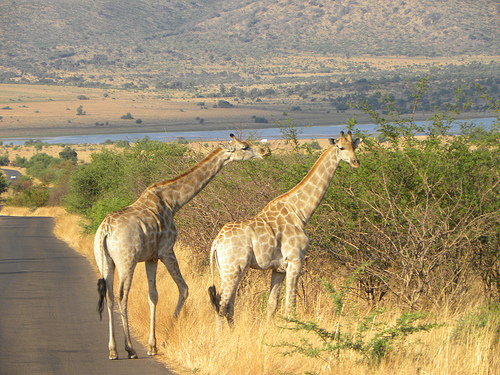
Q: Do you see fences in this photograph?
A: No, there are no fences.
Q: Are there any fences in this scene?
A: No, there are no fences.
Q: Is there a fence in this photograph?
A: No, there are no fences.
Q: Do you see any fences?
A: No, there are no fences.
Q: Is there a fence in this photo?
A: No, there are no fences.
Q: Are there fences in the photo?
A: No, there are no fences.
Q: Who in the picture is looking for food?
A: The animal is looking for food.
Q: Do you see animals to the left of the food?
A: Yes, there is an animal to the left of the food.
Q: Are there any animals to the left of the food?
A: Yes, there is an animal to the left of the food.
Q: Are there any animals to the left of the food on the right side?
A: Yes, there is an animal to the left of the food.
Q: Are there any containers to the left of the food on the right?
A: No, there is an animal to the left of the food.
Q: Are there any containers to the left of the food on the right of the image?
A: No, there is an animal to the left of the food.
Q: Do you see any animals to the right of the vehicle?
A: Yes, there is an animal to the right of the vehicle.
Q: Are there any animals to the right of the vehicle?
A: Yes, there is an animal to the right of the vehicle.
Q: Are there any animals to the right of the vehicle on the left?
A: Yes, there is an animal to the right of the vehicle.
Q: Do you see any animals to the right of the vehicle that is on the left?
A: Yes, there is an animal to the right of the vehicle.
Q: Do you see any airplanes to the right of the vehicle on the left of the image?
A: No, there is an animal to the right of the vehicle.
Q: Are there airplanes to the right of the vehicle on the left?
A: No, there is an animal to the right of the vehicle.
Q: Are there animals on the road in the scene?
A: Yes, there is an animal on the road.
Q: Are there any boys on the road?
A: No, there is an animal on the road.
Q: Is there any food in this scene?
A: Yes, there is food.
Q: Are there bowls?
A: No, there are no bowls.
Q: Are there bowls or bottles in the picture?
A: No, there are no bowls or bottles.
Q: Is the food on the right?
A: Yes, the food is on the right of the image.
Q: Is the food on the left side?
A: No, the food is on the right of the image.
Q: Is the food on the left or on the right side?
A: The food is on the right of the image.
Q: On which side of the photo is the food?
A: The food is on the right of the image.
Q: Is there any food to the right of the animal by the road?
A: Yes, there is food to the right of the animal.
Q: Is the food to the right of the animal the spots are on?
A: Yes, the food is to the right of the animal.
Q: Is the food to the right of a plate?
A: No, the food is to the right of the animal.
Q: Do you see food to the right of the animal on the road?
A: Yes, there is food to the right of the animal.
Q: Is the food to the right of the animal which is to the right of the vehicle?
A: Yes, the food is to the right of the animal.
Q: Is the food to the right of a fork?
A: No, the food is to the right of the animal.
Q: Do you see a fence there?
A: No, there are no fences.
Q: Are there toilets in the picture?
A: No, there are no toilets.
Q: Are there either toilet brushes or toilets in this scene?
A: No, there are no toilets or toilet brushes.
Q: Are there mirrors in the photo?
A: No, there are no mirrors.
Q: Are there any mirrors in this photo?
A: No, there are no mirrors.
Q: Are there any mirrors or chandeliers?
A: No, there are no mirrors or chandeliers.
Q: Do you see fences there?
A: No, there are no fences.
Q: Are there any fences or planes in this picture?
A: No, there are no fences or planes.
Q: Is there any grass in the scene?
A: Yes, there is grass.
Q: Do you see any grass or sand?
A: Yes, there is grass.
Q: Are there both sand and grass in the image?
A: No, there is grass but no sand.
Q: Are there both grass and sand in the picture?
A: No, there is grass but no sand.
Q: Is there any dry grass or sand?
A: Yes, there is dry grass.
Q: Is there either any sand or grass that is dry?
A: Yes, the grass is dry.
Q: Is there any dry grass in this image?
A: Yes, there is dry grass.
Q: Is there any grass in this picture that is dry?
A: Yes, there is grass that is dry.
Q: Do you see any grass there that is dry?
A: Yes, there is grass that is dry.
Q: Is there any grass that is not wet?
A: Yes, there is dry grass.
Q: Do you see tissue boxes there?
A: No, there are no tissue boxes.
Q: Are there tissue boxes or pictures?
A: No, there are no tissue boxes or pictures.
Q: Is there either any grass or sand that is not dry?
A: No, there is grass but it is dry.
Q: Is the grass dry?
A: Yes, the grass is dry.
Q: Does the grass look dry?
A: Yes, the grass is dry.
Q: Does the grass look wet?
A: No, the grass is dry.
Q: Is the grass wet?
A: No, the grass is dry.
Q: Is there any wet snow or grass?
A: No, there is grass but it is dry.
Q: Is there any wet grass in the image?
A: No, there is grass but it is dry.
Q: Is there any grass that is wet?
A: No, there is grass but it is dry.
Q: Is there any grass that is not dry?
A: No, there is grass but it is dry.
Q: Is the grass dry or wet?
A: The grass is dry.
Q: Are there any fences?
A: No, there are no fences.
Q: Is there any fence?
A: No, there are no fences.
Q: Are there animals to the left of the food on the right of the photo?
A: Yes, there is an animal to the left of the food.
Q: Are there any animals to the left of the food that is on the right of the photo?
A: Yes, there is an animal to the left of the food.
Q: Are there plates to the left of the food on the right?
A: No, there is an animal to the left of the food.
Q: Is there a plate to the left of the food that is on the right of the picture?
A: No, there is an animal to the left of the food.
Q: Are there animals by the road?
A: Yes, there is an animal by the road.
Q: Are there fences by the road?
A: No, there is an animal by the road.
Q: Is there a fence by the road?
A: No, there is an animal by the road.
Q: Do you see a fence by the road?
A: No, there is an animal by the road.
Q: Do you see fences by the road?
A: No, there is an animal by the road.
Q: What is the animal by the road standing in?
A: The animal is standing in the grass.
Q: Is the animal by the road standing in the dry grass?
A: Yes, the animal is standing in the grass.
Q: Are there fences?
A: No, there are no fences.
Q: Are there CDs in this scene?
A: No, there are no cds.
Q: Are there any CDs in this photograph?
A: No, there are no cds.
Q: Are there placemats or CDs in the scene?
A: No, there are no CDs or placemats.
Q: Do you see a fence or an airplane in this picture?
A: No, there are no fences or airplanes.